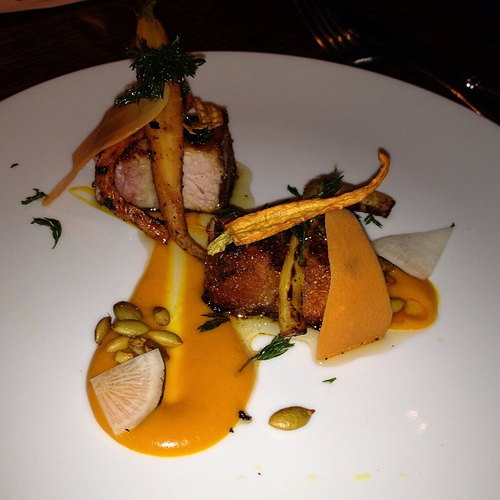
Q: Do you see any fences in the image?
A: No, there are no fences.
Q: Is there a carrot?
A: Yes, there is a carrot.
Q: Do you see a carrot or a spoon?
A: Yes, there is a carrot.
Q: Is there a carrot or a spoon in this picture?
A: Yes, there is a carrot.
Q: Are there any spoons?
A: No, there are no spoons.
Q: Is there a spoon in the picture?
A: No, there are no spoons.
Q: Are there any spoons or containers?
A: No, there are no spoons or containers.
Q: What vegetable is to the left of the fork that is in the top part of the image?
A: The vegetable is a carrot.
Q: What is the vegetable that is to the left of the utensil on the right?
A: The vegetable is a carrot.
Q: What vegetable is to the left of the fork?
A: The vegetable is a carrot.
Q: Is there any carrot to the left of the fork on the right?
A: Yes, there is a carrot to the left of the fork.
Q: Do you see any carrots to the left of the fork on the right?
A: Yes, there is a carrot to the left of the fork.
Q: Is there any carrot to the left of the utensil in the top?
A: Yes, there is a carrot to the left of the fork.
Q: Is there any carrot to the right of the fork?
A: No, the carrot is to the left of the fork.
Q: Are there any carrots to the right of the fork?
A: No, the carrot is to the left of the fork.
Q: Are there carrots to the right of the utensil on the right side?
A: No, the carrot is to the left of the fork.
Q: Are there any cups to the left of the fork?
A: No, there is a carrot to the left of the fork.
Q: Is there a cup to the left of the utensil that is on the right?
A: No, there is a carrot to the left of the fork.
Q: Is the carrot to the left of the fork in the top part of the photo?
A: Yes, the carrot is to the left of the fork.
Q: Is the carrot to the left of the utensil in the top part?
A: Yes, the carrot is to the left of the fork.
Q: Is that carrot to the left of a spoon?
A: No, the carrot is to the left of the fork.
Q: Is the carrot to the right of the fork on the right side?
A: No, the carrot is to the left of the fork.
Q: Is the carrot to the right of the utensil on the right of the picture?
A: No, the carrot is to the left of the fork.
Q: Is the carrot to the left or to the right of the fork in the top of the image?
A: The carrot is to the left of the fork.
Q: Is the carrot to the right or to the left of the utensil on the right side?
A: The carrot is to the left of the fork.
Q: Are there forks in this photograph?
A: Yes, there is a fork.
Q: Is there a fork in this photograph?
A: Yes, there is a fork.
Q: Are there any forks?
A: Yes, there is a fork.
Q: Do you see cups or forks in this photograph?
A: Yes, there is a fork.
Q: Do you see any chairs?
A: No, there are no chairs.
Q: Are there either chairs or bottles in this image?
A: No, there are no chairs or bottles.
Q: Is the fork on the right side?
A: Yes, the fork is on the right of the image.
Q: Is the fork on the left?
A: No, the fork is on the right of the image.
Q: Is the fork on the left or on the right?
A: The fork is on the right of the image.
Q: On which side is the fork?
A: The fork is on the right of the image.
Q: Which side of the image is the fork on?
A: The fork is on the right of the image.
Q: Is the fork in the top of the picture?
A: Yes, the fork is in the top of the image.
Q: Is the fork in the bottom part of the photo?
A: No, the fork is in the top of the image.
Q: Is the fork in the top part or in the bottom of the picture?
A: The fork is in the top of the image.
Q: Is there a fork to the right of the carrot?
A: Yes, there is a fork to the right of the carrot.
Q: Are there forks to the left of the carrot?
A: No, the fork is to the right of the carrot.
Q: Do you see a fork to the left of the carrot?
A: No, the fork is to the right of the carrot.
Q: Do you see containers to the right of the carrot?
A: No, there is a fork to the right of the carrot.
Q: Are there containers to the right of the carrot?
A: No, there is a fork to the right of the carrot.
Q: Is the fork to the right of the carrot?
A: Yes, the fork is to the right of the carrot.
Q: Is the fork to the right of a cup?
A: No, the fork is to the right of the carrot.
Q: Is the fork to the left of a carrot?
A: No, the fork is to the right of a carrot.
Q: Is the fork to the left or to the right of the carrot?
A: The fork is to the right of the carrot.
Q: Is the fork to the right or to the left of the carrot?
A: The fork is to the right of the carrot.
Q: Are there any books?
A: No, there are no books.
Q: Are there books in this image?
A: No, there are no books.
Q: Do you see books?
A: No, there are no books.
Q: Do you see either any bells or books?
A: No, there are no books or bells.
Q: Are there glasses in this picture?
A: No, there are no glasses.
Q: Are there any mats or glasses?
A: No, there are no glasses or mats.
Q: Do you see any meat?
A: Yes, there is meat.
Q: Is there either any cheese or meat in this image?
A: Yes, there is meat.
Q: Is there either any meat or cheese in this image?
A: Yes, there is meat.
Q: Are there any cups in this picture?
A: No, there are no cups.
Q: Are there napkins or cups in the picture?
A: No, there are no cups or napkins.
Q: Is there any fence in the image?
A: No, there are no fences.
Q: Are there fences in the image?
A: No, there are no fences.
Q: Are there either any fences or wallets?
A: No, there are no fences or wallets.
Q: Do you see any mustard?
A: Yes, there is mustard.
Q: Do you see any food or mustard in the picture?
A: Yes, there is mustard.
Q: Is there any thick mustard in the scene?
A: Yes, there is thick mustard.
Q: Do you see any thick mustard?
A: Yes, there is thick mustard.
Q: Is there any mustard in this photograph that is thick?
A: Yes, there is mustard that is thick.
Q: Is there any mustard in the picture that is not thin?
A: Yes, there is thick mustard.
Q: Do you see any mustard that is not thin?
A: Yes, there is thick mustard.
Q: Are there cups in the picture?
A: No, there are no cups.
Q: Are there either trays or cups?
A: No, there are no cups or trays.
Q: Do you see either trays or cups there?
A: No, there are no cups or trays.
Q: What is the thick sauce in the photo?
A: The sauce is mustard.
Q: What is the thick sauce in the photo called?
A: The sauce is mustard.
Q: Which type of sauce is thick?
A: The sauce is mustard.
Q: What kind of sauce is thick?
A: The sauce is mustard.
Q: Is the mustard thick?
A: Yes, the mustard is thick.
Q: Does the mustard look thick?
A: Yes, the mustard is thick.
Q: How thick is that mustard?
A: The mustard is thick.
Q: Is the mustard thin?
A: No, the mustard is thick.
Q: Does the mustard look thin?
A: No, the mustard is thick.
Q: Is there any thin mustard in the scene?
A: No, there is mustard but it is thick.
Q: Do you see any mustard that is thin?
A: No, there is mustard but it is thick.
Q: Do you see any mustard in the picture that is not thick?
A: No, there is mustard but it is thick.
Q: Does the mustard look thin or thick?
A: The mustard is thick.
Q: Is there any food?
A: Yes, there is food.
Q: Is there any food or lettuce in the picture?
A: Yes, there is food.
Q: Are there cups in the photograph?
A: No, there are no cups.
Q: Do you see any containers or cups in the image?
A: No, there are no cups or containers.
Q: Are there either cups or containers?
A: No, there are no cups or containers.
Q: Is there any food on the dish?
A: Yes, there is food on the dish.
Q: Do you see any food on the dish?
A: Yes, there is food on the dish.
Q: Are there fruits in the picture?
A: Yes, there is a fruit.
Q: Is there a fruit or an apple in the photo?
A: Yes, there is a fruit.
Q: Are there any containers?
A: No, there are no containers.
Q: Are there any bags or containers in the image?
A: No, there are no containers or bags.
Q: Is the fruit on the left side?
A: Yes, the fruit is on the left of the image.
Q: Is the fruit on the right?
A: No, the fruit is on the left of the image.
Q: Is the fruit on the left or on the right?
A: The fruit is on the left of the image.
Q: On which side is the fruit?
A: The fruit is on the left of the image.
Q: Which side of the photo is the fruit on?
A: The fruit is on the left of the image.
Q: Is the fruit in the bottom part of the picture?
A: Yes, the fruit is in the bottom of the image.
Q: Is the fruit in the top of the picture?
A: No, the fruit is in the bottom of the image.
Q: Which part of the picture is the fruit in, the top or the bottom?
A: The fruit is in the bottom of the image.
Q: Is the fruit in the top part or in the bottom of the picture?
A: The fruit is in the bottom of the image.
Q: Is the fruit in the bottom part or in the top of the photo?
A: The fruit is in the bottom of the image.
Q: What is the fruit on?
A: The fruit is on the dish.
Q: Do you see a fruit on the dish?
A: Yes, there is a fruit on the dish.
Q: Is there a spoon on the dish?
A: No, there is a fruit on the dish.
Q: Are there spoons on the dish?
A: No, there is a fruit on the dish.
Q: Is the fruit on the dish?
A: Yes, the fruit is on the dish.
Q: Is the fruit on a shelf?
A: No, the fruit is on the dish.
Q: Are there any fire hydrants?
A: No, there are no fire hydrants.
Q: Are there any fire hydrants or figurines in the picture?
A: No, there are no fire hydrants or figurines.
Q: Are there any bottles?
A: No, there are no bottles.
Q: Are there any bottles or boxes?
A: No, there are no bottles or boxes.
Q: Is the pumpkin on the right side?
A: Yes, the pumpkin is on the right of the image.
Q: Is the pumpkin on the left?
A: No, the pumpkin is on the right of the image.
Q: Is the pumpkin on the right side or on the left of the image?
A: The pumpkin is on the right of the image.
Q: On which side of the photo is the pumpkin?
A: The pumpkin is on the right of the image.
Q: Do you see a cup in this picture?
A: No, there are no cups.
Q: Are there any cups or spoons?
A: No, there are no cups or spoons.